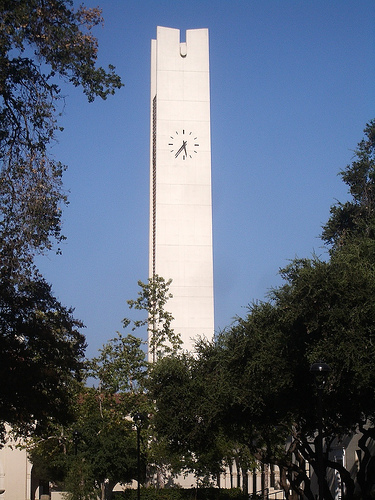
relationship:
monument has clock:
[146, 22, 216, 493] [162, 126, 197, 160]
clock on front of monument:
[166, 127, 201, 156] [140, 18, 223, 455]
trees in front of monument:
[157, 340, 296, 491] [146, 22, 216, 493]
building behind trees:
[303, 415, 364, 487] [141, 268, 351, 477]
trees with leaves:
[9, 6, 126, 443] [5, 15, 132, 490]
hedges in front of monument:
[113, 487, 243, 497] [151, 24, 217, 481]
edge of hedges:
[213, 481, 240, 493] [113, 487, 243, 500]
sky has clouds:
[226, 90, 303, 157] [87, 333, 101, 343]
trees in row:
[127, 285, 372, 438] [140, 360, 371, 488]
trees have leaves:
[157, 342, 225, 489] [205, 343, 294, 407]